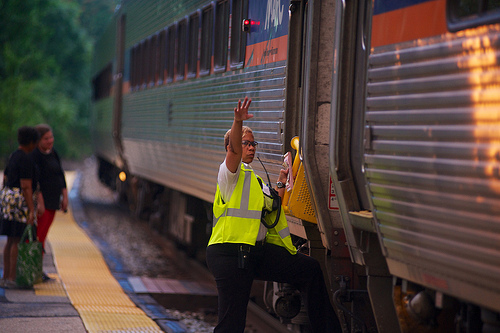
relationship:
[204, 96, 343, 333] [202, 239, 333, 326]
woman wearing pants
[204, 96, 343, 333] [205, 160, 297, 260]
woman wearing vest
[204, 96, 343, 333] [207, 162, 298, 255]
woman wearing green vest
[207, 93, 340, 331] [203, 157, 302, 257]
woman wearing green vest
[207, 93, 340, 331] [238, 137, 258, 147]
woman wearing glasses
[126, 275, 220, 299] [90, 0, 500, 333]
walkway leading to car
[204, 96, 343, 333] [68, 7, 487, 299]
woman getting on train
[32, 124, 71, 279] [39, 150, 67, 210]
woman wearing shirt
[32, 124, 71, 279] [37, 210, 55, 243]
woman wearing pants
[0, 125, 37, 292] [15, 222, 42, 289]
woman holding bag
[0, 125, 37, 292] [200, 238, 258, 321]
woman wearing pants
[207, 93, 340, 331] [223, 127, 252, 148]
woman raising hair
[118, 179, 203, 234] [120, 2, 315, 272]
wheels underneath car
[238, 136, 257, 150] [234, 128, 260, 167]
glasses on face